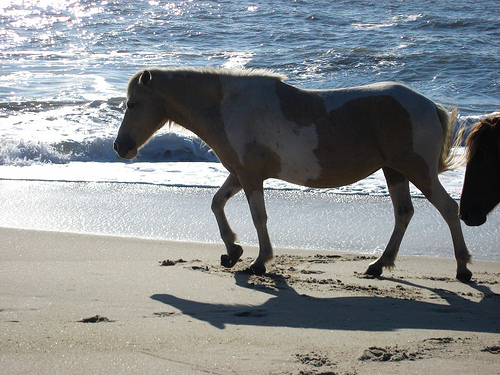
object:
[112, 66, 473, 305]
horse beach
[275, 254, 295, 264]
print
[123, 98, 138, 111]
eye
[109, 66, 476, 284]
horse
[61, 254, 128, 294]
sand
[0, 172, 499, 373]
shore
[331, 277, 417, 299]
tracks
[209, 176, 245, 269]
front legs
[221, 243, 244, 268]
foot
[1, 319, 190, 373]
sand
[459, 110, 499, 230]
horse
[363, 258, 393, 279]
back foot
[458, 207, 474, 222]
nose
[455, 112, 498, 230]
brown head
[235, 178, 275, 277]
leg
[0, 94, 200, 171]
wave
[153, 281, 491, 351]
dirt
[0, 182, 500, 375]
beach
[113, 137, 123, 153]
nose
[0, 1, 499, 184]
lake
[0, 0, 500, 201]
water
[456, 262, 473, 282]
foot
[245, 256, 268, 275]
foot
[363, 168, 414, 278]
back legs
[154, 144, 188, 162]
patch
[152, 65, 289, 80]
hair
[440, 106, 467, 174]
tail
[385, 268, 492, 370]
sand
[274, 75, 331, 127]
spot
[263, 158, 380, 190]
stomach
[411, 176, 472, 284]
leg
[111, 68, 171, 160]
head